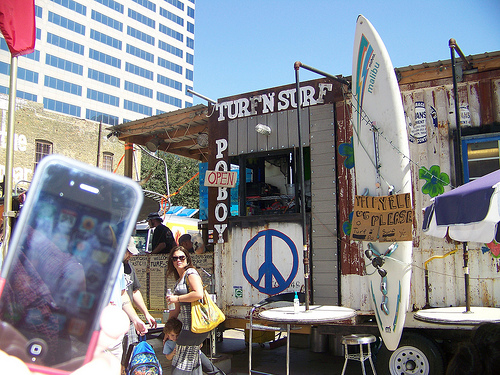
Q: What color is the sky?
A: Blue.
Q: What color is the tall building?
A: Blue and white.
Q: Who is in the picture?
A: 3 tourist.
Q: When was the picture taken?
A: In the daytime.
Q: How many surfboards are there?
A: 1.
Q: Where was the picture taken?
A: By a restaurant.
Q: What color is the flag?
A: Red.